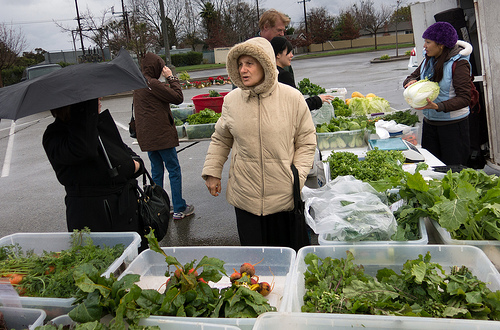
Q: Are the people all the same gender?
A: No, they are both male and female.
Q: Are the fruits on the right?
A: Yes, the fruits are on the right of the image.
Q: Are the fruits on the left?
A: No, the fruits are on the right of the image.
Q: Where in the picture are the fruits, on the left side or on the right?
A: The fruits are on the right of the image.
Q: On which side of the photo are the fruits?
A: The fruits are on the right of the image.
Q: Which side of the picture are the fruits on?
A: The fruits are on the right of the image.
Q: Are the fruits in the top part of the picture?
A: Yes, the fruits are in the top of the image.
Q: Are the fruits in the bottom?
A: No, the fruits are in the top of the image.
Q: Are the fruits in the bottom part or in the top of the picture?
A: The fruits are in the top of the image.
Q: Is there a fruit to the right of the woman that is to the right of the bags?
A: Yes, there are fruits to the right of the woman.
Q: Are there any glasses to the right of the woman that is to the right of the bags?
A: No, there are fruits to the right of the woman.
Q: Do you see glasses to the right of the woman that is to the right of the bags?
A: No, there are fruits to the right of the woman.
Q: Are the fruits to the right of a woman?
A: Yes, the fruits are to the right of a woman.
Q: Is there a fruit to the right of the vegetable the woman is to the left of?
A: Yes, there are fruits to the right of the vegetable.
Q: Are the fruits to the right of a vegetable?
A: Yes, the fruits are to the right of a vegetable.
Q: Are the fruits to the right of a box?
A: No, the fruits are to the right of a vegetable.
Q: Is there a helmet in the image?
A: No, there are no helmets.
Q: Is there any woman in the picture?
A: Yes, there is a woman.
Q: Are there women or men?
A: Yes, there is a woman.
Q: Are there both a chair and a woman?
A: No, there is a woman but no chairs.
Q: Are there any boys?
A: No, there are no boys.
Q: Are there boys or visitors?
A: No, there are no boys or visitors.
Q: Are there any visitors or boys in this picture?
A: No, there are no boys or visitors.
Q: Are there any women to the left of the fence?
A: Yes, there is a woman to the left of the fence.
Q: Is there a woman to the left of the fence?
A: Yes, there is a woman to the left of the fence.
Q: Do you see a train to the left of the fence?
A: No, there is a woman to the left of the fence.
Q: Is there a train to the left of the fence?
A: No, there is a woman to the left of the fence.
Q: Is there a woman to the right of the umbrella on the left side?
A: Yes, there is a woman to the right of the umbrella.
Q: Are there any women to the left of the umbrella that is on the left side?
A: No, the woman is to the right of the umbrella.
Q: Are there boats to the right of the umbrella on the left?
A: No, there is a woman to the right of the umbrella.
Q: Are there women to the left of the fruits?
A: Yes, there is a woman to the left of the fruits.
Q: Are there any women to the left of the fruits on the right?
A: Yes, there is a woman to the left of the fruits.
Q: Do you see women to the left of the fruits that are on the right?
A: Yes, there is a woman to the left of the fruits.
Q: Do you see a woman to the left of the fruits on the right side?
A: Yes, there is a woman to the left of the fruits.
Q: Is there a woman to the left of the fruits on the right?
A: Yes, there is a woman to the left of the fruits.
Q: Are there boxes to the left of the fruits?
A: No, there is a woman to the left of the fruits.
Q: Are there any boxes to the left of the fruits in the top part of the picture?
A: No, there is a woman to the left of the fruits.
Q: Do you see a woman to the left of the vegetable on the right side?
A: Yes, there is a woman to the left of the vegetable.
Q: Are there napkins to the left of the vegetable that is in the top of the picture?
A: No, there is a woman to the left of the vegetable.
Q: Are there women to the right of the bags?
A: Yes, there is a woman to the right of the bags.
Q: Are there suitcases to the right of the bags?
A: No, there is a woman to the right of the bags.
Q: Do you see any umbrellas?
A: Yes, there is an umbrella.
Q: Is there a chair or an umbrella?
A: Yes, there is an umbrella.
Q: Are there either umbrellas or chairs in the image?
A: Yes, there is an umbrella.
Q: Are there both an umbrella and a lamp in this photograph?
A: No, there is an umbrella but no lamps.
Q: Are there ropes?
A: No, there are no ropes.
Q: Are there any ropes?
A: No, there are no ropes.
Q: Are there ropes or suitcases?
A: No, there are no ropes or suitcases.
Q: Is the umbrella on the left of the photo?
A: Yes, the umbrella is on the left of the image.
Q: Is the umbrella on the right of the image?
A: No, the umbrella is on the left of the image.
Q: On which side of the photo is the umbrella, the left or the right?
A: The umbrella is on the left of the image.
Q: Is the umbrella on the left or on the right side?
A: The umbrella is on the left of the image.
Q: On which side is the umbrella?
A: The umbrella is on the left of the image.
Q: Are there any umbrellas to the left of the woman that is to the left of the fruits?
A: Yes, there is an umbrella to the left of the woman.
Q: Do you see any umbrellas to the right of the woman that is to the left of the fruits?
A: No, the umbrella is to the left of the woman.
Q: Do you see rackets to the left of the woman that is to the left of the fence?
A: No, there is an umbrella to the left of the woman.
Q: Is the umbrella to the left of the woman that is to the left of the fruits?
A: Yes, the umbrella is to the left of the woman.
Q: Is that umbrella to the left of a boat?
A: No, the umbrella is to the left of the woman.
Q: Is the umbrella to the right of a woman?
A: No, the umbrella is to the left of a woman.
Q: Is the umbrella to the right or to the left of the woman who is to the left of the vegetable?
A: The umbrella is to the left of the woman.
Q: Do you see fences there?
A: Yes, there is a fence.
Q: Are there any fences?
A: Yes, there is a fence.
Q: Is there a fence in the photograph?
A: Yes, there is a fence.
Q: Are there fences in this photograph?
A: Yes, there is a fence.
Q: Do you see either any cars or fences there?
A: Yes, there is a fence.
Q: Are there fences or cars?
A: Yes, there is a fence.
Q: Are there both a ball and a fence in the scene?
A: No, there is a fence but no balls.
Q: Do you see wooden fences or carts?
A: Yes, there is a wood fence.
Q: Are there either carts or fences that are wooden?
A: Yes, the fence is wooden.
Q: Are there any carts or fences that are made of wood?
A: Yes, the fence is made of wood.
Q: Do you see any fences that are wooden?
A: Yes, there is a wood fence.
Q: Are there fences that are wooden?
A: Yes, there is a fence that is wooden.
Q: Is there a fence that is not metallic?
A: Yes, there is a wooden fence.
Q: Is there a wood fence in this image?
A: Yes, there is a fence that is made of wood.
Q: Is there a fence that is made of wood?
A: Yes, there is a fence that is made of wood.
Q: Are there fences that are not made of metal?
A: Yes, there is a fence that is made of wood.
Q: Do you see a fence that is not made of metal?
A: Yes, there is a fence that is made of wood.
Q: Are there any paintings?
A: No, there are no paintings.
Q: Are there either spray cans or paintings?
A: No, there are no paintings or spray cans.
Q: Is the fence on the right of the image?
A: Yes, the fence is on the right of the image.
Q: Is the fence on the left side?
A: No, the fence is on the right of the image.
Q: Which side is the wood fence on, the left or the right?
A: The fence is on the right of the image.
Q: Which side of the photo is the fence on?
A: The fence is on the right of the image.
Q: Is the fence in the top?
A: Yes, the fence is in the top of the image.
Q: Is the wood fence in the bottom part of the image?
A: No, the fence is in the top of the image.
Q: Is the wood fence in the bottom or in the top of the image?
A: The fence is in the top of the image.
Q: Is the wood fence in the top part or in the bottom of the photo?
A: The fence is in the top of the image.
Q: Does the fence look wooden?
A: Yes, the fence is wooden.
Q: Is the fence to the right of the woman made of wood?
A: Yes, the fence is made of wood.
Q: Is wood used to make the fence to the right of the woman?
A: Yes, the fence is made of wood.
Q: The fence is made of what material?
A: The fence is made of wood.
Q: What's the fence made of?
A: The fence is made of wood.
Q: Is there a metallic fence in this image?
A: No, there is a fence but it is wooden.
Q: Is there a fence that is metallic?
A: No, there is a fence but it is wooden.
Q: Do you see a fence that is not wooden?
A: No, there is a fence but it is wooden.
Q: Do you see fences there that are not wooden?
A: No, there is a fence but it is wooden.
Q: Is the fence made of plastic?
A: No, the fence is made of wood.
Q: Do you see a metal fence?
A: No, there is a fence but it is made of wood.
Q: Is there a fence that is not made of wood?
A: No, there is a fence but it is made of wood.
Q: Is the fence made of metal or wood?
A: The fence is made of wood.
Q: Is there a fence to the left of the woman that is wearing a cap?
A: Yes, there is a fence to the left of the woman.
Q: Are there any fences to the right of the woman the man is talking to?
A: No, the fence is to the left of the woman.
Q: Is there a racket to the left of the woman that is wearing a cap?
A: No, there is a fence to the left of the woman.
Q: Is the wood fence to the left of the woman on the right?
A: Yes, the fence is to the left of the woman.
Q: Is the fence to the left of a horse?
A: No, the fence is to the left of the woman.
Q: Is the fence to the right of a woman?
A: No, the fence is to the left of a woman.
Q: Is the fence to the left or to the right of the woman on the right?
A: The fence is to the left of the woman.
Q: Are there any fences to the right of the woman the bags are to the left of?
A: Yes, there is a fence to the right of the woman.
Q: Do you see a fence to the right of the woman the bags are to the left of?
A: Yes, there is a fence to the right of the woman.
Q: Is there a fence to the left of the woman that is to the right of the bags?
A: No, the fence is to the right of the woman.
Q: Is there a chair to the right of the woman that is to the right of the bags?
A: No, there is a fence to the right of the woman.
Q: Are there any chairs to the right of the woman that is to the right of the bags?
A: No, there is a fence to the right of the woman.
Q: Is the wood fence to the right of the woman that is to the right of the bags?
A: Yes, the fence is to the right of the woman.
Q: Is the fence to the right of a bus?
A: No, the fence is to the right of the woman.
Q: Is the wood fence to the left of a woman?
A: No, the fence is to the right of a woman.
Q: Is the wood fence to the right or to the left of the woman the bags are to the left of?
A: The fence is to the right of the woman.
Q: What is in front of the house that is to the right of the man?
A: The fence is in front of the house.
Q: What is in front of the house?
A: The fence is in front of the house.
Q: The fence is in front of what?
A: The fence is in front of the house.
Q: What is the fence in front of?
A: The fence is in front of the house.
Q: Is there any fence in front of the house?
A: Yes, there is a fence in front of the house.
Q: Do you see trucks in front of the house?
A: No, there is a fence in front of the house.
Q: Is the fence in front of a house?
A: Yes, the fence is in front of a house.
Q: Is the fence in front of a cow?
A: No, the fence is in front of a house.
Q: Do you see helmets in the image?
A: No, there are no helmets.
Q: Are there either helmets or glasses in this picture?
A: No, there are no helmets or glasses.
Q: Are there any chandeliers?
A: No, there are no chandeliers.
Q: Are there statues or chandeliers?
A: No, there are no chandeliers or statues.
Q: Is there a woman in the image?
A: Yes, there is a woman.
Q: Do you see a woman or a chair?
A: Yes, there is a woman.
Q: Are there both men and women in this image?
A: Yes, there are both a woman and a man.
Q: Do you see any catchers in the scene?
A: No, there are no catchers.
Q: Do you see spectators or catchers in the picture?
A: No, there are no catchers or spectators.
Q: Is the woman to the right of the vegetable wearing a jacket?
A: Yes, the woman is wearing a jacket.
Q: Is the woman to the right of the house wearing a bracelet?
A: No, the woman is wearing a jacket.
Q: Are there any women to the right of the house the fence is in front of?
A: Yes, there is a woman to the right of the house.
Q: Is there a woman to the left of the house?
A: No, the woman is to the right of the house.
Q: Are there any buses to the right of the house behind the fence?
A: No, there is a woman to the right of the house.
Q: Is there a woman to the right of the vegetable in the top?
A: Yes, there is a woman to the right of the vegetable.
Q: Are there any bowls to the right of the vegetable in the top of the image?
A: No, there is a woman to the right of the vegetable.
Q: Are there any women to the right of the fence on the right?
A: Yes, there is a woman to the right of the fence.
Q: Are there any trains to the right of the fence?
A: No, there is a woman to the right of the fence.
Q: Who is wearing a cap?
A: The woman is wearing a cap.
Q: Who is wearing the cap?
A: The woman is wearing a cap.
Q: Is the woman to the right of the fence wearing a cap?
A: Yes, the woman is wearing a cap.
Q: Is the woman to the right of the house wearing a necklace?
A: No, the woman is wearing a cap.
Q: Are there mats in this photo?
A: No, there are no mats.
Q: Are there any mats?
A: No, there are no mats.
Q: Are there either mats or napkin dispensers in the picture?
A: No, there are no mats or napkin dispensers.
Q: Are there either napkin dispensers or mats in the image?
A: No, there are no mats or napkin dispensers.